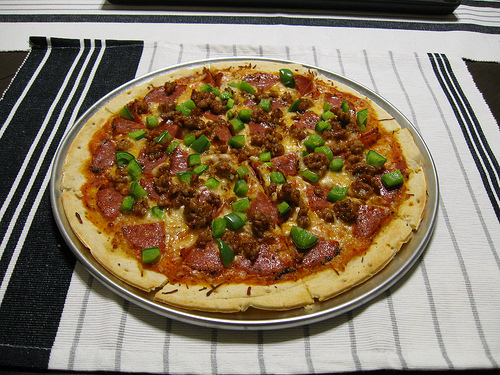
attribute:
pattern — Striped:
[158, 339, 222, 372]